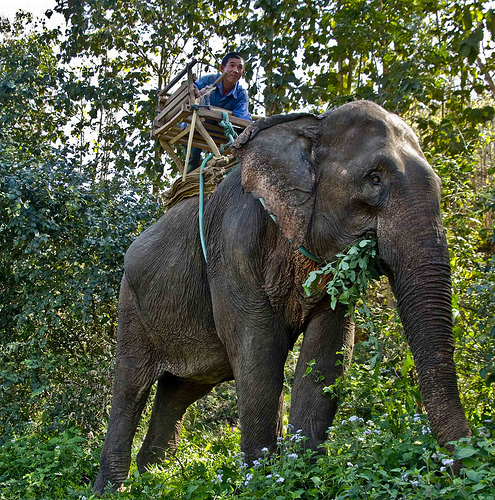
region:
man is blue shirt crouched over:
[193, 47, 251, 117]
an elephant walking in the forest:
[99, 106, 494, 468]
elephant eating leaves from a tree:
[277, 99, 491, 338]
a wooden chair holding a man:
[152, 55, 268, 159]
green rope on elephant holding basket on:
[181, 91, 330, 292]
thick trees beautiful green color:
[5, 73, 93, 367]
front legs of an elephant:
[226, 315, 366, 464]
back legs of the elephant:
[82, 280, 201, 487]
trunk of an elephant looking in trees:
[379, 220, 487, 468]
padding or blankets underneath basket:
[150, 145, 236, 205]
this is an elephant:
[172, 209, 279, 417]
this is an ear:
[220, 119, 385, 407]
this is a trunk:
[378, 206, 439, 456]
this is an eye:
[346, 164, 389, 226]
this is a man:
[156, 42, 279, 201]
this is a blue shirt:
[188, 66, 277, 156]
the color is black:
[100, 250, 324, 341]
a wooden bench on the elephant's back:
[153, 58, 262, 180]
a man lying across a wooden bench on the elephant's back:
[149, 50, 253, 174]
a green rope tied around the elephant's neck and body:
[196, 109, 330, 277]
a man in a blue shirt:
[184, 53, 263, 173]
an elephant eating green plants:
[89, 100, 480, 497]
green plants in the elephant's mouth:
[299, 237, 378, 350]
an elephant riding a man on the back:
[85, 99, 473, 497]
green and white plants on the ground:
[325, 414, 428, 498]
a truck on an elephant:
[385, 276, 473, 479]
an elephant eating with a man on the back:
[86, 51, 479, 495]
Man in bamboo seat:
[179, 51, 254, 124]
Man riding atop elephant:
[145, 46, 316, 266]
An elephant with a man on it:
[85, 45, 476, 476]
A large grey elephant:
[105, 101, 484, 468]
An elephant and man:
[1, 4, 494, 494]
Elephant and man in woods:
[24, 33, 485, 482]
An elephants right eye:
[353, 154, 396, 199]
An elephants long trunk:
[383, 192, 492, 463]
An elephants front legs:
[204, 280, 351, 481]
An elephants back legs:
[80, 282, 208, 489]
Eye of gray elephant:
[364, 169, 387, 190]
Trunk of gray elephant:
[390, 239, 475, 449]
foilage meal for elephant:
[302, 237, 383, 311]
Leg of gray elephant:
[230, 343, 288, 461]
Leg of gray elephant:
[291, 329, 356, 436]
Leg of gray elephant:
[86, 365, 146, 497]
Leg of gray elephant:
[138, 376, 205, 477]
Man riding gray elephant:
[197, 34, 259, 116]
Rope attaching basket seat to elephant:
[191, 171, 215, 263]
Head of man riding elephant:
[215, 51, 251, 89]